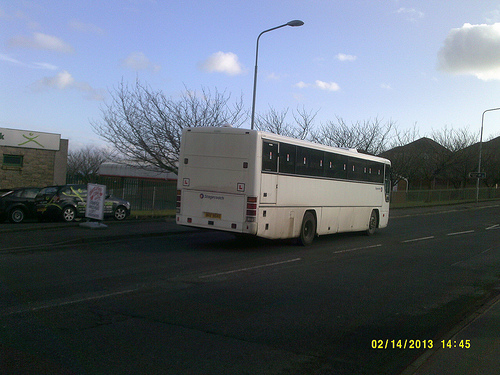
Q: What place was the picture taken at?
A: It was taken at the street.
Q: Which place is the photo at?
A: It is at the street.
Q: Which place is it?
A: It is a street.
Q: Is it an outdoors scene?
A: Yes, it is outdoors.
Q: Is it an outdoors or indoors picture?
A: It is outdoors.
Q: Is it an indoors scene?
A: No, it is outdoors.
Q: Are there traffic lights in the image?
A: No, there are no traffic lights.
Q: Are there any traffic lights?
A: No, there are no traffic lights.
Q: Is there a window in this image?
A: Yes, there is a window.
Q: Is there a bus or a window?
A: Yes, there is a window.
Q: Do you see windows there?
A: Yes, there is a window.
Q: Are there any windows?
A: Yes, there is a window.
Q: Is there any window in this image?
A: Yes, there is a window.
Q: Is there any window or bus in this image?
A: Yes, there is a window.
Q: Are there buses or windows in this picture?
A: Yes, there is a window.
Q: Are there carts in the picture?
A: No, there are no carts.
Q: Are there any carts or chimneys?
A: No, there are no carts or chimneys.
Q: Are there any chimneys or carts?
A: No, there are no carts or chimneys.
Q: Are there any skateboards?
A: No, there are no skateboards.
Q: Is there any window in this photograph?
A: Yes, there is a window.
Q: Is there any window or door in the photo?
A: Yes, there is a window.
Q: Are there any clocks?
A: No, there are no clocks.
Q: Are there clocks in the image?
A: No, there are no clocks.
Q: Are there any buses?
A: Yes, there is a bus.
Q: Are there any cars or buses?
A: Yes, there is a bus.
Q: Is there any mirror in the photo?
A: No, there are no mirrors.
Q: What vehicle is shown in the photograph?
A: The vehicle is a bus.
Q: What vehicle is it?
A: The vehicle is a bus.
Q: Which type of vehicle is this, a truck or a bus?
A: That is a bus.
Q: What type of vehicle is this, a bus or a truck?
A: That is a bus.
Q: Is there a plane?
A: No, there are no airplanes.